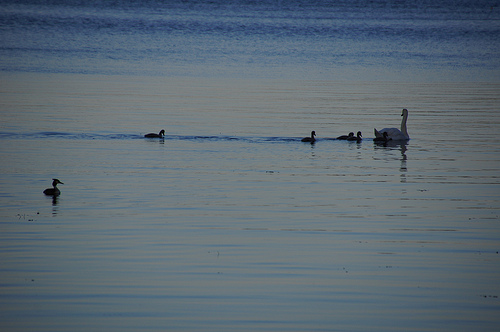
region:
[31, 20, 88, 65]
white clouds in blue sky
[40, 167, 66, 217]
black duck in blue water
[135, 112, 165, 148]
black duck in blue water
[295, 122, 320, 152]
black duck in blue water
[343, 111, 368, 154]
black duck in blue water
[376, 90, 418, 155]
black duck in blue water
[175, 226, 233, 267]
blue water in lake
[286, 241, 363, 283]
blue water in lake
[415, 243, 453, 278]
blue water in lake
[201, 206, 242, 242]
blue water in lake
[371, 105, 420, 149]
swan in the water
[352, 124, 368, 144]
swan in the water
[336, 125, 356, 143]
swan in the water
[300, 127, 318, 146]
swan in the water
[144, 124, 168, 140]
swan in the water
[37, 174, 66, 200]
swan in the water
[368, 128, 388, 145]
swan in the water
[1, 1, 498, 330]
water with swans inside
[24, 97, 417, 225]
swan with her babies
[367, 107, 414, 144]
white swan in the water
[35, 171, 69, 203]
duck in blue water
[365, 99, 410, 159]
duck in blue water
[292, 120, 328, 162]
duck in blue water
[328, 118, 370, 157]
duck in blue water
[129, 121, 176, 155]
duck in blue water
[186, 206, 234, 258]
ripples in white and blue water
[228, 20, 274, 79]
ripples in white and blue water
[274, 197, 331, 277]
ripples in white and blue water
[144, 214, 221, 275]
ripples in white and blue water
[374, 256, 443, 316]
ripples in white and blue water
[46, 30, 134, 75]
blue and white dark water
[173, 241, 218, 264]
blue and white dark water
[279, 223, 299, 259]
blue and white dark water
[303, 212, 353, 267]
blue and white dark water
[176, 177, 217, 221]
blue and white dark water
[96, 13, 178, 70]
blue and white dark water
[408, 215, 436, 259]
blue and white dark water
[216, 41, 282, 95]
blue and white dark water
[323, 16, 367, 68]
blue and white dark water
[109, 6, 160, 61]
blue and white dark water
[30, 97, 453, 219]
ducks in a body of water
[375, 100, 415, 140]
tallest duck in group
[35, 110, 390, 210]
shorter ducks in the group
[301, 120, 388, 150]
ducks closest to white duck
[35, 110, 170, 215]
ducks further away from white duck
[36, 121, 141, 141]
water propelling from ducks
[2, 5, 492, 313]
a mass of water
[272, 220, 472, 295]
waves in the water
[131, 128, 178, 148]
duck with head pointed downward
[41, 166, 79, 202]
duck with head pointing straight